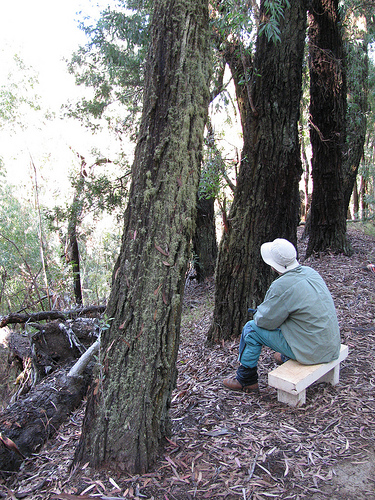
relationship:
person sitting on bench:
[221, 236, 343, 392] [267, 341, 352, 411]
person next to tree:
[221, 236, 343, 392] [69, 1, 234, 480]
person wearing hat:
[221, 236, 343, 392] [261, 238, 302, 273]